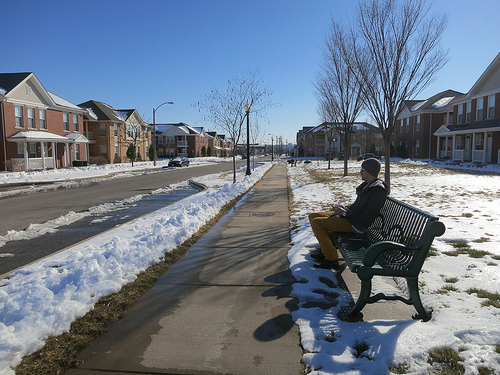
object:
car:
[168, 156, 190, 168]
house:
[294, 121, 390, 160]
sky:
[2, 1, 498, 150]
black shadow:
[251, 253, 326, 342]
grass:
[16, 184, 256, 372]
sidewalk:
[0, 160, 306, 371]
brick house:
[0, 71, 89, 170]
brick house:
[75, 99, 151, 167]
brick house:
[151, 122, 208, 157]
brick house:
[432, 52, 500, 164]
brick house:
[389, 88, 469, 157]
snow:
[286, 156, 498, 371]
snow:
[0, 152, 274, 373]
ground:
[0, 155, 500, 372]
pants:
[308, 211, 357, 261]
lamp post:
[243, 100, 252, 176]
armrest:
[361, 240, 423, 268]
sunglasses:
[360, 167, 366, 172]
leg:
[406, 277, 432, 321]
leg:
[345, 274, 373, 321]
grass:
[1, 143, 279, 373]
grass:
[416, 328, 472, 373]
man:
[308, 157, 390, 268]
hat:
[361, 158, 381, 178]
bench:
[332, 195, 446, 323]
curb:
[122, 155, 203, 175]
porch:
[6, 130, 69, 174]